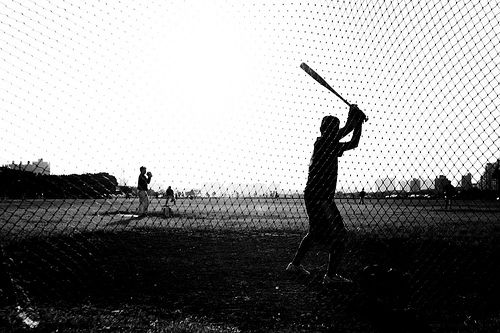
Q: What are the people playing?
A: Baseball.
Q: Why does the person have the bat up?
A: To hit the ball.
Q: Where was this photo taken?
A: Outside at the baseball field.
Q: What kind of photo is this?
A: Black and white.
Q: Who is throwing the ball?
A: The pitcher.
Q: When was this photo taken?
A: During the day.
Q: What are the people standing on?
A: The ground.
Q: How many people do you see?
A: Three.